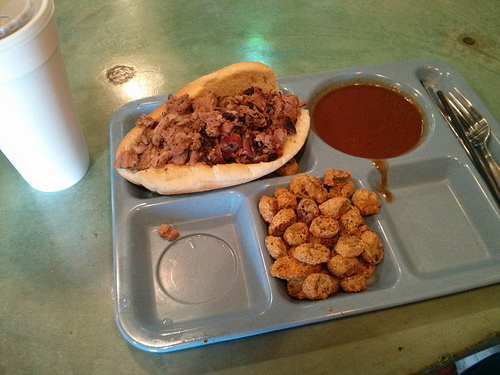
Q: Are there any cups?
A: Yes, there is a cup.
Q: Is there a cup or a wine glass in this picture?
A: Yes, there is a cup.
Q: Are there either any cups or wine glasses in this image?
A: Yes, there is a cup.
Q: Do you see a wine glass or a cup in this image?
A: Yes, there is a cup.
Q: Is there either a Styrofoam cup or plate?
A: Yes, there is a Styrofoam cup.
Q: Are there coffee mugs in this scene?
A: No, there are no coffee mugs.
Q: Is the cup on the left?
A: Yes, the cup is on the left of the image.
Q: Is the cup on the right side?
A: No, the cup is on the left of the image.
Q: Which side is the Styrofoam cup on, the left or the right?
A: The cup is on the left of the image.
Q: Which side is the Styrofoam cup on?
A: The cup is on the left of the image.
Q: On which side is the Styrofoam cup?
A: The cup is on the left of the image.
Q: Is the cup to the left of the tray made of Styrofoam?
A: Yes, the cup is made of styrofoam.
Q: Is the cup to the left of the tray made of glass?
A: No, the cup is made of styrofoam.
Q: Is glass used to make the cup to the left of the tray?
A: No, the cup is made of styrofoam.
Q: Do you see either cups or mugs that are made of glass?
A: No, there is a cup but it is made of styrofoam.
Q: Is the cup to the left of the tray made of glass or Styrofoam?
A: The cup is made of styrofoam.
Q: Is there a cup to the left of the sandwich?
A: Yes, there is a cup to the left of the sandwich.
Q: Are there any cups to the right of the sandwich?
A: No, the cup is to the left of the sandwich.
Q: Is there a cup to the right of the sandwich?
A: No, the cup is to the left of the sandwich.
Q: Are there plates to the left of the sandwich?
A: No, there is a cup to the left of the sandwich.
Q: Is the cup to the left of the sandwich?
A: Yes, the cup is to the left of the sandwich.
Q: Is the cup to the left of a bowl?
A: No, the cup is to the left of the sandwich.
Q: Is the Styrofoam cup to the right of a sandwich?
A: No, the cup is to the left of a sandwich.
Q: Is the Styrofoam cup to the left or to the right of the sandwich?
A: The cup is to the left of the sandwich.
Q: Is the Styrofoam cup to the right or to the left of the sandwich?
A: The cup is to the left of the sandwich.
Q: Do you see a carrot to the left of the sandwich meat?
A: No, there is a cup to the left of the meat.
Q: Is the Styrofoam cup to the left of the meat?
A: Yes, the cup is to the left of the meat.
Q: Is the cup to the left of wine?
A: No, the cup is to the left of the meat.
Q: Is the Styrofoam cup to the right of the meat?
A: No, the cup is to the left of the meat.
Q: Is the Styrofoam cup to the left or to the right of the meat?
A: The cup is to the left of the meat.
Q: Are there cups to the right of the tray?
A: No, the cup is to the left of the tray.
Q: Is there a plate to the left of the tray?
A: No, there is a cup to the left of the tray.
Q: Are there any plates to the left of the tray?
A: No, there is a cup to the left of the tray.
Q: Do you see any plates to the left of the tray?
A: No, there is a cup to the left of the tray.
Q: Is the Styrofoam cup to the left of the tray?
A: Yes, the cup is to the left of the tray.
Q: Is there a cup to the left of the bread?
A: Yes, there is a cup to the left of the bread.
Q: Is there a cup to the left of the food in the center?
A: Yes, there is a cup to the left of the bread.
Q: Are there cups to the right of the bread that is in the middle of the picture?
A: No, the cup is to the left of the bread.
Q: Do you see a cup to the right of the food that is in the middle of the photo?
A: No, the cup is to the left of the bread.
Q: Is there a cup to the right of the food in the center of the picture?
A: No, the cup is to the left of the bread.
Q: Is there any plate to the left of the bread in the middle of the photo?
A: No, there is a cup to the left of the bread.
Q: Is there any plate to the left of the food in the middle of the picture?
A: No, there is a cup to the left of the bread.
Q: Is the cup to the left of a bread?
A: Yes, the cup is to the left of a bread.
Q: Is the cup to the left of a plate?
A: No, the cup is to the left of a bread.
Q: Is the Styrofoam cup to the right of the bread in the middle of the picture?
A: No, the cup is to the left of the bread.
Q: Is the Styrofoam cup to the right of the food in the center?
A: No, the cup is to the left of the bread.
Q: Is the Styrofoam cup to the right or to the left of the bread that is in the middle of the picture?
A: The cup is to the left of the bread.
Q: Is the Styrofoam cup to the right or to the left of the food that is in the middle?
A: The cup is to the left of the bread.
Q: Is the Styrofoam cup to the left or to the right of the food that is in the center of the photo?
A: The cup is to the left of the bread.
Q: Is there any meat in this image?
A: Yes, there is meat.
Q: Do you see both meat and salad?
A: No, there is meat but no salad.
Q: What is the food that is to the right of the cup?
A: The food is meat.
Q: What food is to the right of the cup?
A: The food is meat.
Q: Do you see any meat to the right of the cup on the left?
A: Yes, there is meat to the right of the cup.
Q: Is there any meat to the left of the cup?
A: No, the meat is to the right of the cup.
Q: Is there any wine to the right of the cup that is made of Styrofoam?
A: No, there is meat to the right of the cup.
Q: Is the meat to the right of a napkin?
A: No, the meat is to the right of a cup.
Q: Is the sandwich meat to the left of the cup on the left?
A: No, the meat is to the right of the cup.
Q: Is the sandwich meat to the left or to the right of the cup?
A: The meat is to the right of the cup.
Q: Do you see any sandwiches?
A: Yes, there is a sandwich.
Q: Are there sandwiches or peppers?
A: Yes, there is a sandwich.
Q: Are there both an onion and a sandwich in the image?
A: No, there is a sandwich but no onions.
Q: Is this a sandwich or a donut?
A: This is a sandwich.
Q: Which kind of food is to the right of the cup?
A: The food is a sandwich.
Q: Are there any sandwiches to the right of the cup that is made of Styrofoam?
A: Yes, there is a sandwich to the right of the cup.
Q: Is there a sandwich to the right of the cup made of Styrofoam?
A: Yes, there is a sandwich to the right of the cup.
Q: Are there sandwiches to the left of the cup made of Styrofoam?
A: No, the sandwich is to the right of the cup.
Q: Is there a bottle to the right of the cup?
A: No, there is a sandwich to the right of the cup.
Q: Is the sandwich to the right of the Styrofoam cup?
A: Yes, the sandwich is to the right of the cup.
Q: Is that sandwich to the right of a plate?
A: No, the sandwich is to the right of the cup.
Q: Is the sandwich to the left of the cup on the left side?
A: No, the sandwich is to the right of the cup.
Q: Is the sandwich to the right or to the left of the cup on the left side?
A: The sandwich is to the right of the cup.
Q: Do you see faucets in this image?
A: No, there are no faucets.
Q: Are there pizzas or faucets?
A: No, there are no faucets or pizzas.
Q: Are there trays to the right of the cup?
A: Yes, there is a tray to the right of the cup.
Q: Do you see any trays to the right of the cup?
A: Yes, there is a tray to the right of the cup.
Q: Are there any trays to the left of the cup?
A: No, the tray is to the right of the cup.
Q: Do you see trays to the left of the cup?
A: No, the tray is to the right of the cup.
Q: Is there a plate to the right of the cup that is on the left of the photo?
A: No, there is a tray to the right of the cup.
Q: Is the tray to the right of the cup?
A: Yes, the tray is to the right of the cup.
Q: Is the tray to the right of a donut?
A: No, the tray is to the right of the cup.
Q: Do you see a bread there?
A: Yes, there is a bread.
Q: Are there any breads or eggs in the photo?
A: Yes, there is a bread.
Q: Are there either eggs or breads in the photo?
A: Yes, there is a bread.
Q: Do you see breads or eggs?
A: Yes, there is a bread.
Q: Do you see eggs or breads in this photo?
A: Yes, there is a bread.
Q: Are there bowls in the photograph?
A: No, there are no bowls.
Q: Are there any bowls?
A: No, there are no bowls.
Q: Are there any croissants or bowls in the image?
A: No, there are no bowls or croissants.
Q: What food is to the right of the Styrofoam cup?
A: The food is a bread.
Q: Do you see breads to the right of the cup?
A: Yes, there is a bread to the right of the cup.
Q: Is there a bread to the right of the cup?
A: Yes, there is a bread to the right of the cup.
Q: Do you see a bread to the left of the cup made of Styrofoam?
A: No, the bread is to the right of the cup.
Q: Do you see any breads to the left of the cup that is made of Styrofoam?
A: No, the bread is to the right of the cup.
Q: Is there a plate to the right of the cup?
A: No, there is a bread to the right of the cup.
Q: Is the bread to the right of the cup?
A: Yes, the bread is to the right of the cup.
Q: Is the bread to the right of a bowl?
A: No, the bread is to the right of the cup.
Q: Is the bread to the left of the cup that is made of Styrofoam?
A: No, the bread is to the right of the cup.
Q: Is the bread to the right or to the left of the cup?
A: The bread is to the right of the cup.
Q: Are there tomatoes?
A: No, there are no tomatoes.